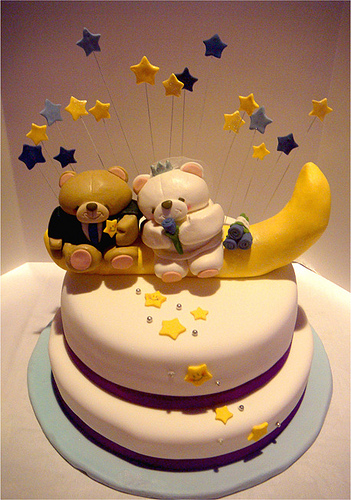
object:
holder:
[162, 219, 183, 254]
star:
[122, 54, 162, 86]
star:
[87, 88, 113, 131]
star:
[301, 92, 334, 125]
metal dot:
[137, 288, 142, 294]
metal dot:
[175, 299, 182, 310]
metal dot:
[146, 314, 153, 324]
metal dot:
[192, 324, 200, 336]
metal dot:
[215, 380, 220, 387]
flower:
[221, 214, 254, 251]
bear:
[131, 156, 231, 282]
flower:
[161, 216, 183, 254]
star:
[192, 25, 226, 67]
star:
[254, 143, 273, 162]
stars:
[16, 138, 50, 170]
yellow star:
[64, 94, 88, 118]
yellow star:
[88, 96, 112, 119]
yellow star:
[26, 121, 49, 143]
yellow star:
[129, 55, 159, 85]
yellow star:
[162, 70, 184, 97]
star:
[274, 133, 299, 153]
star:
[221, 111, 244, 132]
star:
[131, 55, 158, 84]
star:
[74, 27, 102, 54]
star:
[220, 111, 244, 136]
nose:
[85, 202, 98, 211]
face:
[183, 363, 213, 387]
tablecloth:
[0, 259, 351, 499]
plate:
[26, 323, 334, 496]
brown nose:
[161, 199, 172, 209]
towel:
[223, 217, 247, 241]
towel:
[235, 233, 255, 250]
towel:
[221, 235, 237, 252]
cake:
[43, 163, 333, 475]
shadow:
[71, 278, 231, 300]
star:
[131, 282, 269, 447]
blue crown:
[150, 159, 172, 178]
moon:
[43, 163, 332, 280]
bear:
[42, 166, 140, 273]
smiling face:
[189, 369, 204, 381]